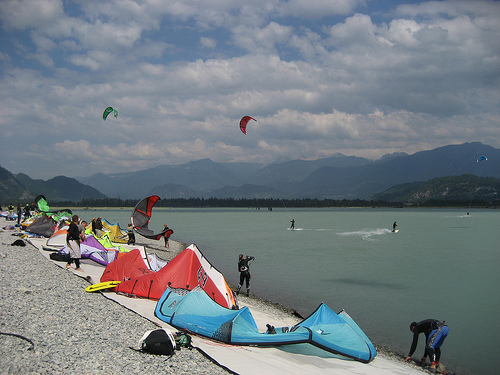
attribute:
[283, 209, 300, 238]
person — kite surfing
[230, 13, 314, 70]
sky — blue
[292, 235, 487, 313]
water — on the surface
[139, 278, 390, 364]
kite — flying, blue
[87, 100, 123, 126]
kite — green, flown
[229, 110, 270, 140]
kite — red, orange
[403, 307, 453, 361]
guy — bent down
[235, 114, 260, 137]
kite — red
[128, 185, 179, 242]
kite — black, red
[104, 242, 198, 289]
kite — red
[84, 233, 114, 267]
kite — purple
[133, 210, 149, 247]
kite — gray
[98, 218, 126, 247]
kite — yellow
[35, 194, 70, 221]
kite — green